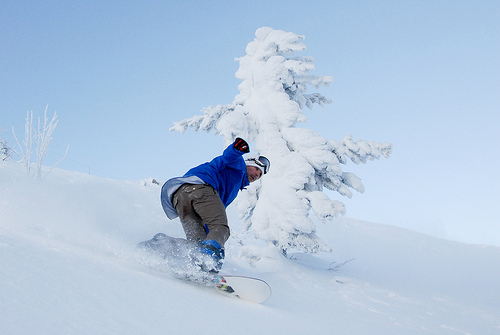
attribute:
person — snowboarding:
[168, 140, 271, 288]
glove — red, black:
[227, 131, 257, 155]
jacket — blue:
[191, 152, 248, 202]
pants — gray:
[168, 180, 231, 256]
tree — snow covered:
[5, 96, 77, 214]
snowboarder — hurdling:
[160, 139, 272, 301]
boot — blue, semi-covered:
[195, 238, 226, 286]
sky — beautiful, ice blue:
[54, 17, 157, 109]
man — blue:
[151, 134, 276, 276]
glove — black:
[222, 132, 267, 159]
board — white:
[217, 269, 275, 311]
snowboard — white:
[224, 267, 275, 305]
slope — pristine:
[11, 161, 131, 319]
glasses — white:
[241, 151, 273, 176]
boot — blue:
[188, 237, 230, 284]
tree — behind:
[170, 23, 391, 261]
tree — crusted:
[165, 19, 402, 281]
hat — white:
[246, 144, 295, 180]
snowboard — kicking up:
[143, 268, 270, 305]